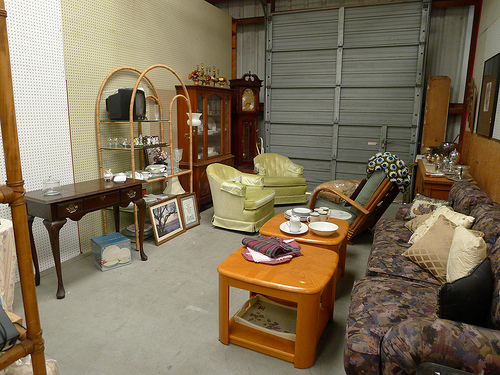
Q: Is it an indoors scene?
A: Yes, it is indoors.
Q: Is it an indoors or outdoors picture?
A: It is indoors.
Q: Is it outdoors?
A: No, it is indoors.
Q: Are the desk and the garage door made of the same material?
A: No, the desk is made of wood and the garage door is made of metal.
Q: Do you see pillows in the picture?
A: Yes, there are pillows.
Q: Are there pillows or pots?
A: Yes, there are pillows.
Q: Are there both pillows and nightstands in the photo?
A: No, there are pillows but no nightstands.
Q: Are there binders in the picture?
A: No, there are no binders.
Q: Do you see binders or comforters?
A: No, there are no binders or comforters.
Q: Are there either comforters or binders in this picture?
A: No, there are no binders or comforters.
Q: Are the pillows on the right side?
A: Yes, the pillows are on the right of the image.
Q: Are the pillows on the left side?
A: No, the pillows are on the right of the image.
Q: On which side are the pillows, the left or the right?
A: The pillows are on the right of the image.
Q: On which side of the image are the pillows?
A: The pillows are on the right of the image.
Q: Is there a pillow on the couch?
A: Yes, there are pillows on the couch.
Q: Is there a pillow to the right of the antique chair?
A: Yes, there are pillows to the right of the chair.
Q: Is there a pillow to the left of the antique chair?
A: No, the pillows are to the right of the chair.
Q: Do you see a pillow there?
A: Yes, there is a pillow.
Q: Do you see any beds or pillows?
A: Yes, there is a pillow.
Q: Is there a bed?
A: No, there are no beds.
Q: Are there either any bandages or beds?
A: No, there are no beds or bandages.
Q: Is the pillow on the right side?
A: Yes, the pillow is on the right of the image.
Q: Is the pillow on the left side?
A: No, the pillow is on the right of the image.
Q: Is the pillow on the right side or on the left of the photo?
A: The pillow is on the right of the image.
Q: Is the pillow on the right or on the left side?
A: The pillow is on the right of the image.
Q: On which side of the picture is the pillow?
A: The pillow is on the right of the image.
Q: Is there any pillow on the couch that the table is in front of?
A: Yes, there is a pillow on the couch.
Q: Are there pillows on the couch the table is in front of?
A: Yes, there is a pillow on the couch.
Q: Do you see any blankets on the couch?
A: No, there is a pillow on the couch.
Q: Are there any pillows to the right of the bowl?
A: Yes, there is a pillow to the right of the bowl.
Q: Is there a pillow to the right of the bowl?
A: Yes, there is a pillow to the right of the bowl.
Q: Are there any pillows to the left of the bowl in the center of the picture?
A: No, the pillow is to the right of the bowl.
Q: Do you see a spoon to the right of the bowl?
A: No, there is a pillow to the right of the bowl.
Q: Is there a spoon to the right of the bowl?
A: No, there is a pillow to the right of the bowl.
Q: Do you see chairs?
A: Yes, there is a chair.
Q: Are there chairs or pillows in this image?
A: Yes, there is a chair.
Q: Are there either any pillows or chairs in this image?
A: Yes, there is a chair.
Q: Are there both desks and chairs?
A: Yes, there are both a chair and a desk.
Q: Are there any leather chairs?
A: Yes, there is a chair that is made of leather.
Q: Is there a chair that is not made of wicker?
A: Yes, there is a chair that is made of leather.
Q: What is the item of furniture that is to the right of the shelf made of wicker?
A: The piece of furniture is a chair.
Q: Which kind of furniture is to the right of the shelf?
A: The piece of furniture is a chair.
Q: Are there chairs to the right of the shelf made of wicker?
A: Yes, there is a chair to the right of the shelf.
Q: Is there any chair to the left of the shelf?
A: No, the chair is to the right of the shelf.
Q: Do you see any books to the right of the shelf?
A: No, there is a chair to the right of the shelf.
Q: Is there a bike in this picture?
A: No, there are no bikes.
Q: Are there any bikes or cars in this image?
A: No, there are no bikes or cars.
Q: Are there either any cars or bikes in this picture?
A: No, there are no bikes or cars.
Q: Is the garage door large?
A: Yes, the garage door is large.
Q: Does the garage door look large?
A: Yes, the garage door is large.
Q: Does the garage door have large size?
A: Yes, the garage door is large.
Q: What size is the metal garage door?
A: The garage door is large.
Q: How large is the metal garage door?
A: The garage door is large.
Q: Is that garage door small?
A: No, the garage door is large.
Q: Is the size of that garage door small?
A: No, the garage door is large.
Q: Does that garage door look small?
A: No, the garage door is large.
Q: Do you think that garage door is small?
A: No, the garage door is large.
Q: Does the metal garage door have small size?
A: No, the garage door is large.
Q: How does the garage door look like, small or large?
A: The garage door is large.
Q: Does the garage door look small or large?
A: The garage door is large.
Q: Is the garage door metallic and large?
A: Yes, the garage door is metallic and large.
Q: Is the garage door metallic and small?
A: No, the garage door is metallic but large.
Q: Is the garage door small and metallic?
A: No, the garage door is metallic but large.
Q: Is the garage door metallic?
A: Yes, the garage door is metallic.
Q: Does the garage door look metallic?
A: Yes, the garage door is metallic.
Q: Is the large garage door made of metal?
A: Yes, the garage door is made of metal.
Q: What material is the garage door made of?
A: The garage door is made of metal.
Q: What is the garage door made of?
A: The garage door is made of metal.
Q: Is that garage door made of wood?
A: No, the garage door is made of metal.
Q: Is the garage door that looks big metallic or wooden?
A: The garage door is metallic.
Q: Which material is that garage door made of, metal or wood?
A: The garage door is made of metal.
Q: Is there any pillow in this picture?
A: Yes, there is a pillow.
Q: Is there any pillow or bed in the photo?
A: Yes, there is a pillow.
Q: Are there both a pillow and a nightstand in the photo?
A: No, there is a pillow but no nightstands.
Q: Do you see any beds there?
A: No, there are no beds.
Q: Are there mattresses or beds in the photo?
A: No, there are no beds or mattresses.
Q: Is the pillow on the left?
A: No, the pillow is on the right of the image.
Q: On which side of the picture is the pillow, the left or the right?
A: The pillow is on the right of the image.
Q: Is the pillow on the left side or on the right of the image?
A: The pillow is on the right of the image.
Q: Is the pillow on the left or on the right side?
A: The pillow is on the right of the image.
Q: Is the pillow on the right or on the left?
A: The pillow is on the right of the image.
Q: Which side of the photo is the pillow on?
A: The pillow is on the right of the image.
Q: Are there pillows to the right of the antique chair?
A: Yes, there is a pillow to the right of the chair.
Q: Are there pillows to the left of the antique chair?
A: No, the pillow is to the right of the chair.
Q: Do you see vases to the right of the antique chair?
A: No, there is a pillow to the right of the chair.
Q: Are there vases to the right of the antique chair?
A: No, there is a pillow to the right of the chair.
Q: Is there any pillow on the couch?
A: Yes, there is a pillow on the couch.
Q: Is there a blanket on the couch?
A: No, there is a pillow on the couch.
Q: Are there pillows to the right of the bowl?
A: Yes, there is a pillow to the right of the bowl.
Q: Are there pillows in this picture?
A: Yes, there is a pillow.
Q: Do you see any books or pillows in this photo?
A: Yes, there is a pillow.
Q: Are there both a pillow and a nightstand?
A: No, there is a pillow but no nightstands.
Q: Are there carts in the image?
A: No, there are no carts.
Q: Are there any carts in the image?
A: No, there are no carts.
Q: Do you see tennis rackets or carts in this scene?
A: No, there are no carts or tennis rackets.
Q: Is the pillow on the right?
A: Yes, the pillow is on the right of the image.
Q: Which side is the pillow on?
A: The pillow is on the right of the image.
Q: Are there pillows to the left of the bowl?
A: No, the pillow is to the right of the bowl.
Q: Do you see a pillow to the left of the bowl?
A: No, the pillow is to the right of the bowl.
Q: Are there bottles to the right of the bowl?
A: No, there is a pillow to the right of the bowl.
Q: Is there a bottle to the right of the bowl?
A: No, there is a pillow to the right of the bowl.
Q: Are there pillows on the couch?
A: Yes, there is a pillow on the couch.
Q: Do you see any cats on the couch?
A: No, there is a pillow on the couch.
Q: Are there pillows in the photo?
A: Yes, there is a pillow.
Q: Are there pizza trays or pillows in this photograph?
A: Yes, there is a pillow.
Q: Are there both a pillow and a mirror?
A: No, there is a pillow but no mirrors.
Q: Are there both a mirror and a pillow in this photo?
A: No, there is a pillow but no mirrors.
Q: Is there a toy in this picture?
A: No, there are no toys.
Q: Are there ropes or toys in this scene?
A: No, there are no toys or ropes.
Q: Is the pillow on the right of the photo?
A: Yes, the pillow is on the right of the image.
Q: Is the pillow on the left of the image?
A: No, the pillow is on the right of the image.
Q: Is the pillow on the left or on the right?
A: The pillow is on the right of the image.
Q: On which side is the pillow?
A: The pillow is on the right of the image.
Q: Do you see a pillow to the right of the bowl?
A: Yes, there is a pillow to the right of the bowl.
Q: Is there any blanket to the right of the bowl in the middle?
A: No, there is a pillow to the right of the bowl.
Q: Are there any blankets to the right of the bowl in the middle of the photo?
A: No, there is a pillow to the right of the bowl.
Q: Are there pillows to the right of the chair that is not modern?
A: Yes, there is a pillow to the right of the chair.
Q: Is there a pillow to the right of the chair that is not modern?
A: Yes, there is a pillow to the right of the chair.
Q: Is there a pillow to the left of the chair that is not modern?
A: No, the pillow is to the right of the chair.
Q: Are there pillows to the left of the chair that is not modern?
A: No, the pillow is to the right of the chair.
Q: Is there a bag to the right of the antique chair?
A: No, there is a pillow to the right of the chair.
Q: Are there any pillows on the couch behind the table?
A: Yes, there is a pillow on the couch.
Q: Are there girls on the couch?
A: No, there is a pillow on the couch.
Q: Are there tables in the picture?
A: Yes, there is a table.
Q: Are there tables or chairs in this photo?
A: Yes, there is a table.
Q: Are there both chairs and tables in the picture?
A: Yes, there are both a table and a chair.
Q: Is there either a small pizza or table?
A: Yes, there is a small table.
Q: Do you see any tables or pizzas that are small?
A: Yes, the table is small.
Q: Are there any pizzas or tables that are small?
A: Yes, the table is small.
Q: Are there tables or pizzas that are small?
A: Yes, the table is small.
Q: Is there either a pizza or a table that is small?
A: Yes, the table is small.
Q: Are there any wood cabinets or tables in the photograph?
A: Yes, there is a wood table.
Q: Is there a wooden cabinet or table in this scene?
A: Yes, there is a wood table.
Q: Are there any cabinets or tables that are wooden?
A: Yes, the table is wooden.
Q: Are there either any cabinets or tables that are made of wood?
A: Yes, the table is made of wood.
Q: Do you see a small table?
A: Yes, there is a small table.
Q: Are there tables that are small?
A: Yes, there is a table that is small.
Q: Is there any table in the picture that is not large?
A: Yes, there is a small table.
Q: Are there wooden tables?
A: Yes, there is a wood table.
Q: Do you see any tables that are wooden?
A: Yes, there is a wood table.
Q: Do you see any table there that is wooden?
A: Yes, there is a table that is wooden.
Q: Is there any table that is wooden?
A: Yes, there is a table that is wooden.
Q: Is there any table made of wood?
A: Yes, there is a table that is made of wood.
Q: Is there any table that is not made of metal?
A: Yes, there is a table that is made of wood.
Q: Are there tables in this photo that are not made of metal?
A: Yes, there is a table that is made of wood.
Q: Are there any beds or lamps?
A: No, there are no lamps or beds.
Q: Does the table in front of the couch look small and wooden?
A: Yes, the table is small and wooden.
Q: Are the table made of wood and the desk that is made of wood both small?
A: Yes, both the table and the desk are small.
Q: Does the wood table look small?
A: Yes, the table is small.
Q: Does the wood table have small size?
A: Yes, the table is small.